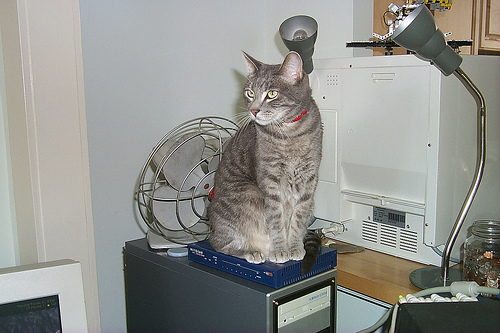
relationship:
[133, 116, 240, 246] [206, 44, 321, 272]
fan behind cat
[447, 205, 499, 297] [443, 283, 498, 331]
jar on desk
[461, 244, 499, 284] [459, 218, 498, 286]
coins inside jar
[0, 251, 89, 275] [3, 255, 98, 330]
edge of frame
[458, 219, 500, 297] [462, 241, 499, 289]
jar with change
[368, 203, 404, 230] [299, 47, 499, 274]
plate on fridge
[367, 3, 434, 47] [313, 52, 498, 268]
figure on fridge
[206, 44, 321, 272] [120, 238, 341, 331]
cat sitting on computer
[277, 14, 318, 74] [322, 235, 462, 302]
lamp on desk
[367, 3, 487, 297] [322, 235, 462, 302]
lamp on desk